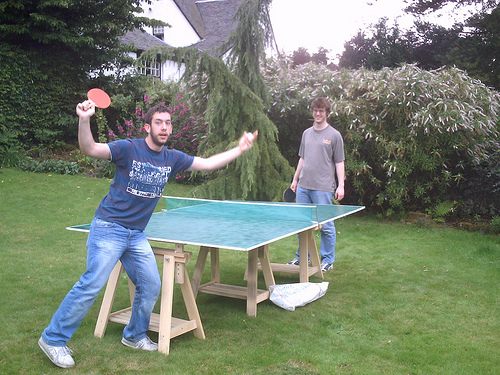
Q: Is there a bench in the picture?
A: No, there are no benches.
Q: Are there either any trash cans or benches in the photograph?
A: No, there are no benches or trash cans.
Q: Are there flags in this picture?
A: No, there are no flags.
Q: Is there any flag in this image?
A: No, there are no flags.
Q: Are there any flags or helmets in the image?
A: No, there are no flags or helmets.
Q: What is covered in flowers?
A: The shrub is covered in flowers.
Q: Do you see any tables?
A: Yes, there is a table.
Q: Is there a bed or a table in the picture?
A: Yes, there is a table.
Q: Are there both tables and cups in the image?
A: No, there is a table but no cups.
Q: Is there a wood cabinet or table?
A: Yes, there is a wood table.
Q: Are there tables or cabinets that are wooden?
A: Yes, the table is wooden.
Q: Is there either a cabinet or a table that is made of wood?
A: Yes, the table is made of wood.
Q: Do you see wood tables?
A: Yes, there is a wood table.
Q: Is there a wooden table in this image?
A: Yes, there is a wood table.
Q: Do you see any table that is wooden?
A: Yes, there is a table that is wooden.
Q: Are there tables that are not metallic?
A: Yes, there is a wooden table.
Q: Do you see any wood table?
A: Yes, there is a table that is made of wood.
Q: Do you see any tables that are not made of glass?
A: Yes, there is a table that is made of wood.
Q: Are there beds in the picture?
A: No, there are no beds.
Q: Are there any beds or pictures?
A: No, there are no beds or pictures.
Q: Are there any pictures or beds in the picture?
A: No, there are no beds or pictures.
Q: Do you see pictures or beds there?
A: No, there are no beds or pictures.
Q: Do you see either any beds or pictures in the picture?
A: No, there are no beds or pictures.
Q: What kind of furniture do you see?
A: The furniture is a table.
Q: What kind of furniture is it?
A: The piece of furniture is a table.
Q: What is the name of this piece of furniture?
A: This is a table.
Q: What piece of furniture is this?
A: This is a table.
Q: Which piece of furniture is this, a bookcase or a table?
A: This is a table.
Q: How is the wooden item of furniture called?
A: The piece of furniture is a table.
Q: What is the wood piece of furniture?
A: The piece of furniture is a table.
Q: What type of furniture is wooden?
A: The furniture is a table.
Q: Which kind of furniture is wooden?
A: The furniture is a table.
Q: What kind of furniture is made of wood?
A: The furniture is a table.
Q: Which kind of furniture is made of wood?
A: The furniture is a table.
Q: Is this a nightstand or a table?
A: This is a table.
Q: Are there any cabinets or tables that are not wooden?
A: No, there is a table but it is wooden.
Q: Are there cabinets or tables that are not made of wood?
A: No, there is a table but it is made of wood.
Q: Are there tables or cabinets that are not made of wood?
A: No, there is a table but it is made of wood.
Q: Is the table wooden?
A: Yes, the table is wooden.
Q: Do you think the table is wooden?
A: Yes, the table is wooden.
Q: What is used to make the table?
A: The table is made of wood.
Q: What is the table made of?
A: The table is made of wood.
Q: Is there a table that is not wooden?
A: No, there is a table but it is wooden.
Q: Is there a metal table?
A: No, there is a table but it is made of wood.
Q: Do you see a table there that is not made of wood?
A: No, there is a table but it is made of wood.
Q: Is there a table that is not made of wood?
A: No, there is a table but it is made of wood.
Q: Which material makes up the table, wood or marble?
A: The table is made of wood.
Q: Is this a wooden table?
A: Yes, this is a wooden table.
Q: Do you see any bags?
A: Yes, there is a bag.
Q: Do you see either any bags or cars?
A: Yes, there is a bag.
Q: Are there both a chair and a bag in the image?
A: No, there is a bag but no chairs.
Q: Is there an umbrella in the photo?
A: No, there are no umbrellas.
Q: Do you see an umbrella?
A: No, there are no umbrellas.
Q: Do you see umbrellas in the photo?
A: No, there are no umbrellas.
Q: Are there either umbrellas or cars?
A: No, there are no umbrellas or cars.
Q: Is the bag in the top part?
A: No, the bag is in the bottom of the image.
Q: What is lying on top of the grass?
A: The bag is lying on top of the grass.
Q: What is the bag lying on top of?
A: The bag is lying on top of the grass.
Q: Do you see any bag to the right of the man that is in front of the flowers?
A: Yes, there is a bag to the right of the man.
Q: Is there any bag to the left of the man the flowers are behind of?
A: No, the bag is to the right of the man.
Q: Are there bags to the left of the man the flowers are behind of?
A: No, the bag is to the right of the man.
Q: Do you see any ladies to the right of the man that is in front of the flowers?
A: No, there is a bag to the right of the man.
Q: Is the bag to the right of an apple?
A: No, the bag is to the right of the man.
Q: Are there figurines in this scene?
A: No, there are no figurines.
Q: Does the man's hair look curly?
A: Yes, the hair is curly.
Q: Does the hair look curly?
A: Yes, the hair is curly.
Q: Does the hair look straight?
A: No, the hair is curly.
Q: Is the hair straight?
A: No, the hair is curly.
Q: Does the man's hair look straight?
A: No, the hair is curly.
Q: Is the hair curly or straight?
A: The hair is curly.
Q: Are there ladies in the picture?
A: No, there are no ladies.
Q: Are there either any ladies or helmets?
A: No, there are no ladies or helmets.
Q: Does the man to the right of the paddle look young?
A: Yes, the man is young.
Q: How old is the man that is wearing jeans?
A: The man is young.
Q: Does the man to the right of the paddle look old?
A: No, the man is young.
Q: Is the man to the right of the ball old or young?
A: The man is young.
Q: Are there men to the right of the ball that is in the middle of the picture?
A: Yes, there is a man to the right of the ball.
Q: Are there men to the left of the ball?
A: No, the man is to the right of the ball.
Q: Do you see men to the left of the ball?
A: No, the man is to the right of the ball.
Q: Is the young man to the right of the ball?
A: Yes, the man is to the right of the ball.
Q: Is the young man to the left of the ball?
A: No, the man is to the right of the ball.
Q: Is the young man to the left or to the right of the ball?
A: The man is to the right of the ball.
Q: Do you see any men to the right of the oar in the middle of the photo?
A: Yes, there is a man to the right of the paddle.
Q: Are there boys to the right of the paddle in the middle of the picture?
A: No, there is a man to the right of the paddle.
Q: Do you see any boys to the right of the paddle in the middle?
A: No, there is a man to the right of the paddle.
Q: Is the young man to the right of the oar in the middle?
A: Yes, the man is to the right of the paddle.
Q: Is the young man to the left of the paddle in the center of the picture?
A: No, the man is to the right of the paddle.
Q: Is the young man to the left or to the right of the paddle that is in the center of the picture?
A: The man is to the right of the paddle.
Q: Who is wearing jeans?
A: The man is wearing jeans.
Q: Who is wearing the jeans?
A: The man is wearing jeans.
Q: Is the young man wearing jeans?
A: Yes, the man is wearing jeans.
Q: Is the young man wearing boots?
A: No, the man is wearing jeans.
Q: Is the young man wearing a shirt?
A: Yes, the man is wearing a shirt.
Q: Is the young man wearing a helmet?
A: No, the man is wearing a shirt.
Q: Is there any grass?
A: Yes, there is grass.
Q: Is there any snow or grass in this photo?
A: Yes, there is grass.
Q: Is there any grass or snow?
A: Yes, there is grass.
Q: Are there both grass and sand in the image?
A: No, there is grass but no sand.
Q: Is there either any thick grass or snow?
A: Yes, there is thick grass.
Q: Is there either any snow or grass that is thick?
A: Yes, the grass is thick.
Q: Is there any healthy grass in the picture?
A: Yes, there is healthy grass.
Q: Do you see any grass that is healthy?
A: Yes, there is grass that is healthy.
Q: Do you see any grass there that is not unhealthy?
A: Yes, there is healthy grass.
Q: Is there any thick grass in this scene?
A: Yes, there is thick grass.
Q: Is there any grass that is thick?
A: Yes, there is grass that is thick.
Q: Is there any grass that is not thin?
A: Yes, there is thick grass.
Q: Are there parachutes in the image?
A: No, there are no parachutes.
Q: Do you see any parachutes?
A: No, there are no parachutes.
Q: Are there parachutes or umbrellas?
A: No, there are no parachutes or umbrellas.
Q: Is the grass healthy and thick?
A: Yes, the grass is healthy and thick.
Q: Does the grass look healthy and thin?
A: No, the grass is healthy but thick.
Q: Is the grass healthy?
A: Yes, the grass is healthy.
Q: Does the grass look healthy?
A: Yes, the grass is healthy.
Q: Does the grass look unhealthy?
A: No, the grass is healthy.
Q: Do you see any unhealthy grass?
A: No, there is grass but it is healthy.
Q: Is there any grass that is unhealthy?
A: No, there is grass but it is healthy.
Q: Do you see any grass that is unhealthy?
A: No, there is grass but it is healthy.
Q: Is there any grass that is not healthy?
A: No, there is grass but it is healthy.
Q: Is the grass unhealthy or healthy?
A: The grass is healthy.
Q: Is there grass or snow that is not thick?
A: No, there is grass but it is thick.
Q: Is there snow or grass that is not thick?
A: No, there is grass but it is thick.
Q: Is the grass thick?
A: Yes, the grass is thick.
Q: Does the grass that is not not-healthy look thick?
A: Yes, the grass is thick.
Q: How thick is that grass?
A: The grass is thick.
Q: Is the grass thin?
A: No, the grass is thick.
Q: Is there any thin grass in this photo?
A: No, there is grass but it is thick.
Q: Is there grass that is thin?
A: No, there is grass but it is thick.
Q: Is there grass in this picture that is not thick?
A: No, there is grass but it is thick.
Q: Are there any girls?
A: No, there are no girls.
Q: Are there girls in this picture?
A: No, there are no girls.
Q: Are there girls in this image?
A: No, there are no girls.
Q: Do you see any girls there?
A: No, there are no girls.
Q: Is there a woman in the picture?
A: No, there are no women.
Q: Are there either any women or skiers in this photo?
A: No, there are no women or skiers.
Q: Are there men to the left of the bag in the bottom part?
A: Yes, there is a man to the left of the bag.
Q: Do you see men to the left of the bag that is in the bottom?
A: Yes, there is a man to the left of the bag.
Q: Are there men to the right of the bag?
A: No, the man is to the left of the bag.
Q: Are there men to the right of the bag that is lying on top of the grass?
A: No, the man is to the left of the bag.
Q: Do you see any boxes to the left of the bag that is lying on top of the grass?
A: No, there is a man to the left of the bag.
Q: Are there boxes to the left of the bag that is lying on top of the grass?
A: No, there is a man to the left of the bag.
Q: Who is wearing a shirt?
A: The man is wearing a shirt.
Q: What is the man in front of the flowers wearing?
A: The man is wearing a shirt.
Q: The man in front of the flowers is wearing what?
A: The man is wearing a shirt.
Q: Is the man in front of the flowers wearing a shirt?
A: Yes, the man is wearing a shirt.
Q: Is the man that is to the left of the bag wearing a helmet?
A: No, the man is wearing a shirt.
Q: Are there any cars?
A: No, there are no cars.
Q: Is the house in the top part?
A: Yes, the house is in the top of the image.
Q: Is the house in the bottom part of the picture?
A: No, the house is in the top of the image.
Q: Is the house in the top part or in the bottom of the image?
A: The house is in the top of the image.